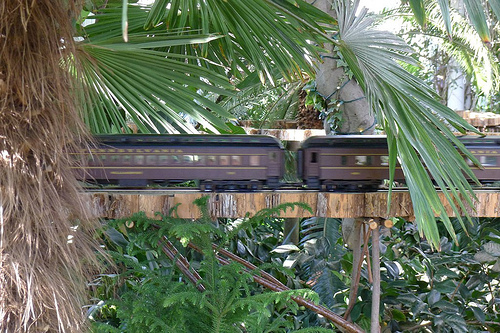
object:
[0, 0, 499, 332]
outdoors